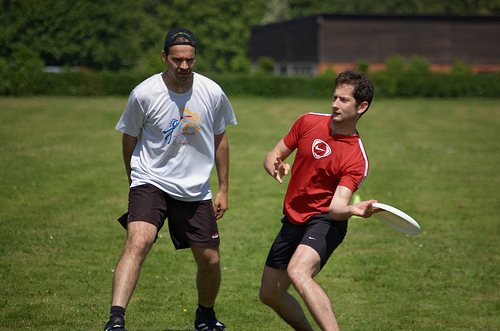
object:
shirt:
[278, 111, 372, 227]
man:
[257, 65, 422, 330]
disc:
[362, 196, 422, 235]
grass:
[1, 98, 98, 329]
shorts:
[263, 209, 348, 272]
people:
[90, 23, 422, 330]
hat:
[163, 25, 200, 44]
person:
[104, 24, 242, 330]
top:
[114, 67, 238, 202]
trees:
[1, 1, 161, 71]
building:
[243, 12, 498, 74]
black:
[309, 220, 341, 236]